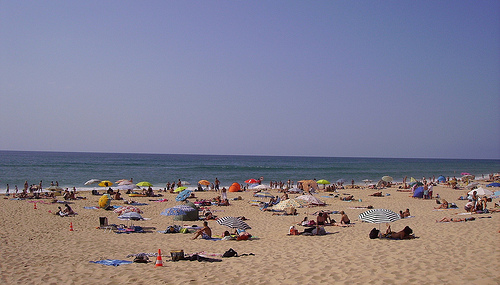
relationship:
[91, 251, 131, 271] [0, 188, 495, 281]
blue blanket in sand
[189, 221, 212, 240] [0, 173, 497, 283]
people in sand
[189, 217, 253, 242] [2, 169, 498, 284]
people on beach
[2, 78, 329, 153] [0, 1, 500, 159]
clouds in clear skies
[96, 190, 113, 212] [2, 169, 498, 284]
man sitting on beach